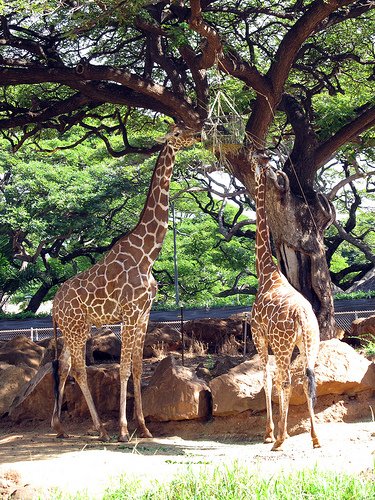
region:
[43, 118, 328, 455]
Two giraffes are standing on the ground.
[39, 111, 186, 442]
A giraffe is looking towards the right.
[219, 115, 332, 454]
A giraffe is looking to the left.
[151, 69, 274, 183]
Food is hanging from a tree.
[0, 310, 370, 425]
Rocks are behind the giraffes.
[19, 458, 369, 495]
Grass is in the foreground.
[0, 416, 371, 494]
The sun is shining on the ground.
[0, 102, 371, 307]
Trees are in the background.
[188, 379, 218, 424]
A rock is casting a shadow.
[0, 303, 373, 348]
A metal fence is behind the rocks.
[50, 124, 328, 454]
two giraffes in the photo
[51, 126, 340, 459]
the two giraffes are feeding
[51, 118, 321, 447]
the giraffes are brown in color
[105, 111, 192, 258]
the giraffe has a tall neck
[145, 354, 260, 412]
the rocks are large in size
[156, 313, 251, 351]
the rocks are arranged in a circle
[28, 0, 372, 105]
the tree has many branches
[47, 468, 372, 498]
the grass are green in color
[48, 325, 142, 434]
the giraffe has long legs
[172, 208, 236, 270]
the trees has green leaves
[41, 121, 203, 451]
a giraffe is eating off a basket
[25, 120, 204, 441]
a giraffe has his head raised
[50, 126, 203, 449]
a giraffe is facing right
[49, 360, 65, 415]
the giraffe's tail is black at the end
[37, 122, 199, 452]
the giraffes is brown and white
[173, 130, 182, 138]
the giraffe has black eyes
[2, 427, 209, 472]
the giraffe is casting a shadow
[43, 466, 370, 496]
grass is seen in front of the picture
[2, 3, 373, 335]
a large tree is behind the giraffes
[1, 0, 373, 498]
the picture was taken outdoors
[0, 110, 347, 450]
two giraffes are feeding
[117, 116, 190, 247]
the giraffe has long neck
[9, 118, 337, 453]
the giraffes color is brown and white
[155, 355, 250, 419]
the rocks are large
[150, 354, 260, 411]
the rocks are brown in color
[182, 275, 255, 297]
the trees are opposite the giraffes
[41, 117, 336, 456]
Two giraffes eating from a tree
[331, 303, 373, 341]
A small fence behind a tree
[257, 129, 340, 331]
A large tree trunk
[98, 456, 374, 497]
Short grass in the dirt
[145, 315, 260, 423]
Tan stones in the shade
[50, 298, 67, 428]
A tail of a giraffe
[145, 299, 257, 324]
Black tarmac behind a gate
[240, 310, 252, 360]
A small light post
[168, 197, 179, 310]
A large pole in the background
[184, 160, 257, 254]
Branches of a tree